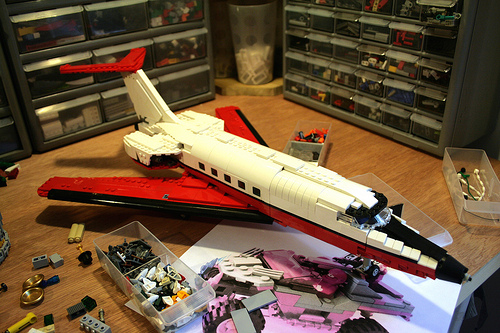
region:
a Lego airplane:
[36, 49, 471, 286]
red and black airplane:
[38, 172, 253, 222]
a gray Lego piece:
[77, 314, 107, 331]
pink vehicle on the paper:
[199, 241, 414, 330]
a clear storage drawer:
[445, 144, 499, 223]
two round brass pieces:
[20, 270, 44, 304]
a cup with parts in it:
[226, 3, 273, 79]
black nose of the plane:
[380, 224, 469, 283]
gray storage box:
[266, 3, 488, 154]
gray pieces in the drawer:
[92, 220, 159, 277]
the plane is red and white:
[28, 45, 475, 297]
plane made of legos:
[25, 42, 476, 291]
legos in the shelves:
[0, 0, 497, 155]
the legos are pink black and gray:
[195, 253, 415, 331]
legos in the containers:
[93, 220, 217, 331]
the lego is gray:
[75, 314, 107, 331]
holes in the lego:
[77, 311, 109, 331]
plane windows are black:
[193, 154, 264, 199]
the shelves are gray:
[0, 2, 499, 153]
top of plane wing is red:
[53, 44, 156, 79]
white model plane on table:
[92, 69, 425, 281]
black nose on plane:
[413, 250, 466, 283]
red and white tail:
[69, 25, 182, 108]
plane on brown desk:
[363, 138, 415, 183]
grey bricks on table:
[12, 239, 95, 319]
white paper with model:
[205, 228, 407, 329]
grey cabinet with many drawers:
[275, 0, 461, 181]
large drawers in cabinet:
[0, 10, 228, 101]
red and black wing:
[208, 95, 268, 175]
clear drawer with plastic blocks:
[95, 225, 202, 332]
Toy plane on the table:
[34, 45, 474, 285]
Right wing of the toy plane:
[37, 172, 274, 226]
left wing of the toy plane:
[211, 104, 270, 149]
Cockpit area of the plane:
[335, 199, 395, 229]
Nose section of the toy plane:
[367, 217, 475, 282]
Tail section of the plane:
[57, 44, 184, 131]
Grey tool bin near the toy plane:
[282, 0, 496, 158]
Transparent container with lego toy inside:
[87, 218, 217, 330]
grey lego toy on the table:
[31, 251, 64, 271]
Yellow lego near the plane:
[66, 222, 85, 243]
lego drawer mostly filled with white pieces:
[34, 94, 106, 141]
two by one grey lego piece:
[30, 253, 47, 269]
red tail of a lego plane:
[60, 46, 145, 74]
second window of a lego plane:
[235, 178, 246, 190]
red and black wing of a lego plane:
[33, 174, 275, 228]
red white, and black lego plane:
[35, 46, 472, 286]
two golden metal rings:
[18, 273, 45, 306]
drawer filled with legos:
[353, 69, 385, 99]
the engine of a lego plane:
[122, 130, 184, 172]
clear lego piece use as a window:
[335, 209, 358, 226]